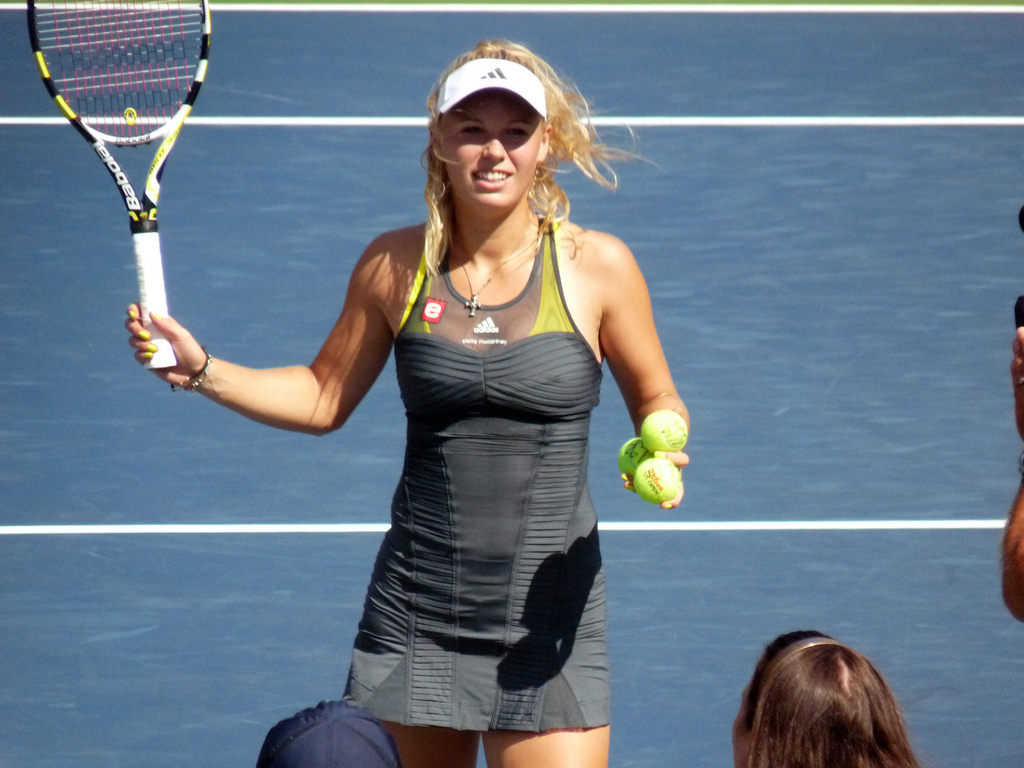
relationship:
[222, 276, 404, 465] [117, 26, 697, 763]
right arm of tennis player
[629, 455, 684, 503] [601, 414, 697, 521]
balls in her hand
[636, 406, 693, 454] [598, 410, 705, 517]
balls in her hand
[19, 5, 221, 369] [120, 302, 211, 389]
racket in her hand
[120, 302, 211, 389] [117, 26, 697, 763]
hand of tennis player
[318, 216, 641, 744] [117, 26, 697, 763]
dress on a tennis player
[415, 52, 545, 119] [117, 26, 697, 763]
visor on a tennis player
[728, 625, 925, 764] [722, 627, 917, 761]
head belonging to woman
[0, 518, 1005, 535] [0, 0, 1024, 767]
line painted on court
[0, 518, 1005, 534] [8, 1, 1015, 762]
line on court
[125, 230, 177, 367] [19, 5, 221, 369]
handle on racket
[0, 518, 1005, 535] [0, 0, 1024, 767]
line on court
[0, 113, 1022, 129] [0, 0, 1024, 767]
line on court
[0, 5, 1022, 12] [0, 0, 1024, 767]
line on court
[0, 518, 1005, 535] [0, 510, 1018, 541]
line on tennis court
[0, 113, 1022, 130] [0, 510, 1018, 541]
line on tennis court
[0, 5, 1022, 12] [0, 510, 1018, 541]
line on tennis court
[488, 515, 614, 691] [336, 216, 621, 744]
shadow on dress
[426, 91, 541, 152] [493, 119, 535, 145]
shadow on eye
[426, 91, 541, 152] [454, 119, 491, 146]
shadow on eye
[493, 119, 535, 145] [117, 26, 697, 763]
eye on tennis player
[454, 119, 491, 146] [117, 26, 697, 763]
eye on tennis player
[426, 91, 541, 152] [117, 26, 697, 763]
shadow on tennis player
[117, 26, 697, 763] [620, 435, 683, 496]
tennis player holding tennis ball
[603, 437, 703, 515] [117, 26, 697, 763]
hand on tennis player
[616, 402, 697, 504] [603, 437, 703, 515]
balls in hand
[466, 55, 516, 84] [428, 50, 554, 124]
logo on visor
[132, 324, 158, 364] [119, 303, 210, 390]
fingernails on hand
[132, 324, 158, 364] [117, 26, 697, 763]
fingernails on tennis player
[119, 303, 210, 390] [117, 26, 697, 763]
hand on tennis player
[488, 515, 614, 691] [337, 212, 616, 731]
shadow on dress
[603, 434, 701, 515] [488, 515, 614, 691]
hand has shadow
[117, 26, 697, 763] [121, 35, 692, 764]
tennis player holding tennis racket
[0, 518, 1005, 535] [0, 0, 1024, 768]
line on ground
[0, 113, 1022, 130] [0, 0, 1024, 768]
line on ground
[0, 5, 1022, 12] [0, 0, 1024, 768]
line on ground